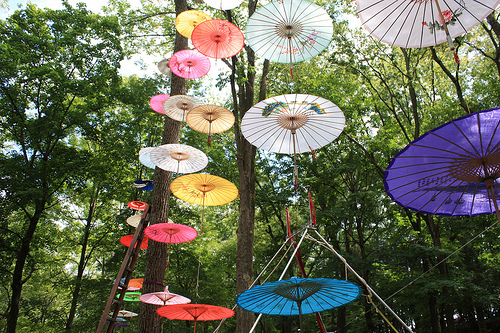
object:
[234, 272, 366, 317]
umbrella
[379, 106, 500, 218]
umbrella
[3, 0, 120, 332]
trees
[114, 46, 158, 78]
sunlight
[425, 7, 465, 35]
rose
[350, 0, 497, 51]
umbrella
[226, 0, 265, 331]
trunk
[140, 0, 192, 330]
tree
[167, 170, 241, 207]
umbrella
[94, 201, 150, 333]
ladder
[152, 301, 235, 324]
umbrella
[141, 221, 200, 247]
umbrella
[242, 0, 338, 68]
umbrella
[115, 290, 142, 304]
umbrella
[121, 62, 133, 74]
sky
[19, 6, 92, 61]
leaves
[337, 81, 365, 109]
leaves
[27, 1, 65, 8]
cloud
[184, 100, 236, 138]
umbrella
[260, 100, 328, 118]
dragon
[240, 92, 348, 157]
parasol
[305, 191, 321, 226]
string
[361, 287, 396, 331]
string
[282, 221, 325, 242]
sticks